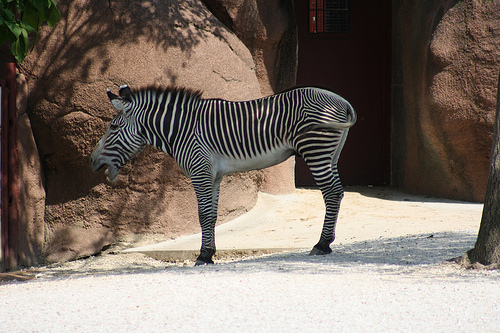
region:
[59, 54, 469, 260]
the zebra has stripes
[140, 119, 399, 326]
the zebra has stripes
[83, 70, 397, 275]
Zebra looking to the left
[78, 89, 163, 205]
Zebra is braying at something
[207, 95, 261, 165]
Black and white pattern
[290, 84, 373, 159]
Tail curved up onto body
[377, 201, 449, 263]
Dirty and rocky ground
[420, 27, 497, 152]
Large rock in background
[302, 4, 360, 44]
Small window in back of enclosure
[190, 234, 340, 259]
Four black hooves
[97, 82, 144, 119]
Upright large ears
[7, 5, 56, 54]
Green leafs on rock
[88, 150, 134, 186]
a mouth open on a zebra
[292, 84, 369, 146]
a zebra tail swishing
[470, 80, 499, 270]
a brown tree trunk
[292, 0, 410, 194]
a doorway in a zebra pen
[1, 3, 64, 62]
green leaves hanging down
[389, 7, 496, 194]
a rock wall in a zebra pen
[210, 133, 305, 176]
a white underbelly on a zebra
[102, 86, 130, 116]
a zebra ear with a black stripe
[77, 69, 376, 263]
a zebrastanding on the ground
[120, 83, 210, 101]
a black and white striped zebra mane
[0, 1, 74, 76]
green leaves from a tree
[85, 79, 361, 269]
a zebra braying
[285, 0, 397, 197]
a brown door in the zebra's enclosure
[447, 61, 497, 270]
a tree trunk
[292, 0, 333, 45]
a small 4 panel window in the brown door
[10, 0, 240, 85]
shadow of leaves and branches being cast onto a rock wall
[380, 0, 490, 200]
a rock wall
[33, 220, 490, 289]
a shadow on the dirt floor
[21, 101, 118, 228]
a crack in the rock wall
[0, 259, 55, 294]
a grate in the dirt floor of the enclosure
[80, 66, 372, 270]
zebra near some rocks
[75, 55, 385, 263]
striped zebra near some rocks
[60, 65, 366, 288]
big zebra near some rocks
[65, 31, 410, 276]
healthy zebra near some rocks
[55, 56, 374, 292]
adult zebra near some rocks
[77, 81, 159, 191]
head of a zebra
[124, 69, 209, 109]
mane of a zebra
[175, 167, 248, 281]
front legs of a zebra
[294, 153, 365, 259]
hind legs of a zebra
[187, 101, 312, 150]
stripes on a zebra